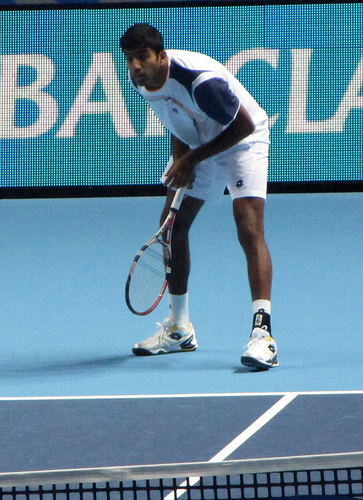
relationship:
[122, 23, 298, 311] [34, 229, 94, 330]
man on court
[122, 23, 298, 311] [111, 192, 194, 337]
man holding racket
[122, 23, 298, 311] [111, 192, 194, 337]
man with racket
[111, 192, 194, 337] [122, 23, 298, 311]
racket on man